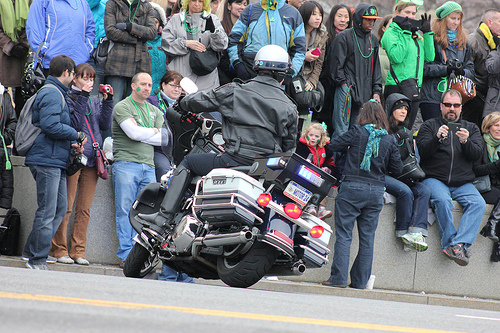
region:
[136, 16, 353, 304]
Motorcycle policeman turning around.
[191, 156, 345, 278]
Emergency medical boxes straddle rear.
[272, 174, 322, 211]
Motorcycle municipal license plate.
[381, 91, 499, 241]
People sitting on cement wall.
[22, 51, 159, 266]
People standing in front cement wall.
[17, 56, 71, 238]
Dark haired man eyeglasses backpack.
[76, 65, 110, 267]
Woman auburn bangs camera ready.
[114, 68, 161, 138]
Green four leaf clover man's face.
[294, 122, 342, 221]
Small blond child looking at patrolman.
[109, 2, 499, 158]
Enough green probably St. Patrick's Day Parade.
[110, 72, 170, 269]
Man in green standing with his arms crossed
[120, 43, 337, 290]
Policeman on a motorcycle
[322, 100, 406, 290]
Woman with blue scarf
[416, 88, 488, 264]
Man holding his cellphone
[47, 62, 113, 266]
Woman holding a red camera and pink purse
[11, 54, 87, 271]
Man wearing a grey backpack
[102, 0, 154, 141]
Woman in a plaid coat crossing her arms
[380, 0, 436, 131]
Woman pulling a scarf onto her face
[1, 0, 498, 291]
Group of people on the side of the road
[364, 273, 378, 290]
Styrofoam white cup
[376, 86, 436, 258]
The woman is sitting.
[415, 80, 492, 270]
The man is sitting.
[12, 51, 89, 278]
The man is standing.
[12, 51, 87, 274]
The man is wearing a backpack.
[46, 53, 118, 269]
The woman is standing.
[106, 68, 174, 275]
The man is standing.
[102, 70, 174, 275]
Man's arms are crossed in front of him.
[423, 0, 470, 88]
The woman is wearing a cap.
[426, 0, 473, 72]
The woman has long hair.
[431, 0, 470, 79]
The woman's cap is green.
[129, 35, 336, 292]
motorcycle turning on street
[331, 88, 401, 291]
woman wearing blue knit scarf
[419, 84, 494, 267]
sitting man wearing dark jacket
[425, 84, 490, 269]
sitting man wearing blue jeans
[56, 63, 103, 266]
woman wearing brown pants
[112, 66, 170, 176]
man wearing green shirt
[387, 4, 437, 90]
woman wearing green coat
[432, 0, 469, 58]
woman wearing green knit hat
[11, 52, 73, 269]
man wearing gray backpack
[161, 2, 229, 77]
woman holding black purse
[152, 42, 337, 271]
police officer on a motorcycle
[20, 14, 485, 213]
spectators on sidewalk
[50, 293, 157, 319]
yellow line painted in middle of the street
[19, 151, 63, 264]
person wearing blue jeans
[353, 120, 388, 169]
scarf around persons neck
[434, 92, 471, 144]
man taking a picture with cell phone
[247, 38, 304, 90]
white helmet on police officer's head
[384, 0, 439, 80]
woman wearing a green jacket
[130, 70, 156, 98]
man witha shamrock painted on his cheek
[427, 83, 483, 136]
man wearing sunglasses